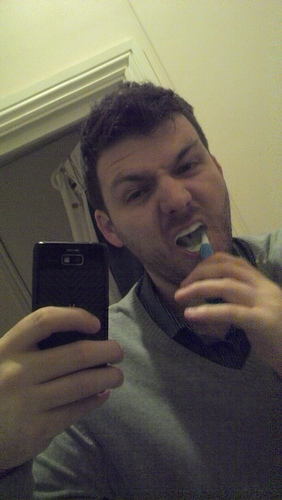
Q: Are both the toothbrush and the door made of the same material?
A: No, the toothbrush is made of plastic and the door is made of wood.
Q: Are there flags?
A: No, there are no flags.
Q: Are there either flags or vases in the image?
A: No, there are no flags or vases.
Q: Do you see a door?
A: Yes, there is a door.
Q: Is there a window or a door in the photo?
A: Yes, there is a door.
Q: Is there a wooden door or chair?
A: Yes, there is a wood door.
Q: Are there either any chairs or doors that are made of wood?
A: Yes, the door is made of wood.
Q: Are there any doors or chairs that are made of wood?
A: Yes, the door is made of wood.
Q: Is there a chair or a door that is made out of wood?
A: Yes, the door is made of wood.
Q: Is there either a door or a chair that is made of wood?
A: Yes, the door is made of wood.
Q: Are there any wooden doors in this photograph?
A: Yes, there is a wood door.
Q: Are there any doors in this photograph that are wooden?
A: Yes, there is a door that is wooden.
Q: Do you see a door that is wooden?
A: Yes, there is a door that is wooden.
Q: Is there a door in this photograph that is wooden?
A: Yes, there is a door that is wooden.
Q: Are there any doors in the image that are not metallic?
A: Yes, there is a wooden door.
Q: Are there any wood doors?
A: Yes, there is a door that is made of wood.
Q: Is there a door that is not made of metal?
A: Yes, there is a door that is made of wood.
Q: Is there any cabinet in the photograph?
A: No, there are no cabinets.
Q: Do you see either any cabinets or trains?
A: No, there are no cabinets or trains.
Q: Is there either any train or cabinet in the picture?
A: No, there are no cabinets or trains.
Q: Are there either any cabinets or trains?
A: No, there are no cabinets or trains.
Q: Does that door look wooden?
A: Yes, the door is wooden.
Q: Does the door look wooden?
A: Yes, the door is wooden.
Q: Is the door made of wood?
A: Yes, the door is made of wood.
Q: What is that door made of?
A: The door is made of wood.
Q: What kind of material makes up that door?
A: The door is made of wood.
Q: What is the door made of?
A: The door is made of wood.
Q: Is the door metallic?
A: No, the door is wooden.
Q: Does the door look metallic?
A: No, the door is wooden.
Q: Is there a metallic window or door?
A: No, there is a door but it is wooden.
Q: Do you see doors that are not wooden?
A: No, there is a door but it is wooden.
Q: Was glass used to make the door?
A: No, the door is made of wood.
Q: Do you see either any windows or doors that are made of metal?
A: No, there is a door but it is made of wood.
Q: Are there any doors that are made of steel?
A: No, there is a door but it is made of wood.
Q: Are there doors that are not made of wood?
A: No, there is a door but it is made of wood.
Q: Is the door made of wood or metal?
A: The door is made of wood.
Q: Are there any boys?
A: No, there are no boys.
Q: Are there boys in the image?
A: No, there are no boys.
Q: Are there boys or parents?
A: No, there are no boys or parents.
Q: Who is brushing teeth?
A: The man is brushing teeth.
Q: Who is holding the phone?
A: The man is holding the telephone.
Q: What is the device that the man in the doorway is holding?
A: The device is a phone.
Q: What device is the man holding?
A: The man is holding the telephone.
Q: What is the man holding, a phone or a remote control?
A: The man is holding a phone.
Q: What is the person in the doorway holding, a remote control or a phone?
A: The man is holding a phone.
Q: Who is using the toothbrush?
A: The man is using the toothbrush.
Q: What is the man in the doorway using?
A: The man is using a toothbrush.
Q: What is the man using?
A: The man is using a toothbrush.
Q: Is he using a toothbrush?
A: Yes, the man is using a toothbrush.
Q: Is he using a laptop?
A: No, the man is using a toothbrush.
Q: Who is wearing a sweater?
A: The man is wearing a sweater.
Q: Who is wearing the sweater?
A: The man is wearing a sweater.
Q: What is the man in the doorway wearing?
A: The man is wearing a sweater.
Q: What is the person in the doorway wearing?
A: The man is wearing a sweater.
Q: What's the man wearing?
A: The man is wearing a sweater.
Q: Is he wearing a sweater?
A: Yes, the man is wearing a sweater.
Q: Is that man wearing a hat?
A: No, the man is wearing a sweater.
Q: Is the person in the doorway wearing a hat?
A: No, the man is wearing a sweater.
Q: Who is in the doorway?
A: The man is in the doorway.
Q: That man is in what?
A: The man is in the doorway.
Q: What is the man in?
A: The man is in the doorway.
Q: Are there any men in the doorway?
A: Yes, there is a man in the doorway.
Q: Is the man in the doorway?
A: Yes, the man is in the doorway.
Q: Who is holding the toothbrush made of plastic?
A: The man is holding the toothbrush.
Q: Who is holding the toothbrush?
A: The man is holding the toothbrush.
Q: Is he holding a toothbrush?
A: Yes, the man is holding a toothbrush.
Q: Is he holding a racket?
A: No, the man is holding a toothbrush.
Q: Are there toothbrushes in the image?
A: Yes, there is a toothbrush.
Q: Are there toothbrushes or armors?
A: Yes, there is a toothbrush.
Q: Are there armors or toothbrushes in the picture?
A: Yes, there is a toothbrush.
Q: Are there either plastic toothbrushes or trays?
A: Yes, there is a plastic toothbrush.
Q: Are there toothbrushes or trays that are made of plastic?
A: Yes, the toothbrush is made of plastic.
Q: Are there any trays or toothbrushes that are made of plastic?
A: Yes, the toothbrush is made of plastic.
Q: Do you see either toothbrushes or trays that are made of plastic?
A: Yes, the toothbrush is made of plastic.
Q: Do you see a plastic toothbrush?
A: Yes, there is a toothbrush that is made of plastic.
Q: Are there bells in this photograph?
A: No, there are no bells.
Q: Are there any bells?
A: No, there are no bells.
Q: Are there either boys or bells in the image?
A: No, there are no bells or boys.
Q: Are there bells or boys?
A: No, there are no bells or boys.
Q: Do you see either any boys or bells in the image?
A: No, there are no bells or boys.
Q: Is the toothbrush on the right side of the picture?
A: Yes, the toothbrush is on the right of the image.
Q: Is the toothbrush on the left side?
A: No, the toothbrush is on the right of the image.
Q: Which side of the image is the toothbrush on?
A: The toothbrush is on the right of the image.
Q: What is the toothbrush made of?
A: The toothbrush is made of plastic.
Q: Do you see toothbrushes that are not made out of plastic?
A: No, there is a toothbrush but it is made of plastic.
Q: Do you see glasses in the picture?
A: No, there are no glasses.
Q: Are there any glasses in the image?
A: No, there are no glasses.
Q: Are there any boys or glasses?
A: No, there are no glasses or boys.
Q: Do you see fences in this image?
A: No, there are no fences.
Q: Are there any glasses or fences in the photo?
A: No, there are no fences or glasses.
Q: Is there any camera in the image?
A: Yes, there is a camera.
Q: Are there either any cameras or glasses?
A: Yes, there is a camera.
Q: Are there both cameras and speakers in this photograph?
A: No, there is a camera but no speakers.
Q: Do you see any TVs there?
A: No, there are no tvs.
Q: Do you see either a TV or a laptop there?
A: No, there are no televisions or laptops.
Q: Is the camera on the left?
A: Yes, the camera is on the left of the image.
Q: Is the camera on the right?
A: No, the camera is on the left of the image.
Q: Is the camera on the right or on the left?
A: The camera is on the left of the image.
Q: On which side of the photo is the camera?
A: The camera is on the left of the image.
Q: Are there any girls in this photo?
A: No, there are no girls.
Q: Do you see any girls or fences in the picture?
A: No, there are no girls or fences.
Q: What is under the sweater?
A: The shirt is under the sweater.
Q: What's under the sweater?
A: The shirt is under the sweater.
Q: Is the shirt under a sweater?
A: Yes, the shirt is under a sweater.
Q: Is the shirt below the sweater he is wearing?
A: Yes, the shirt is below the sweater.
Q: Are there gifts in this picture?
A: No, there are no gifts.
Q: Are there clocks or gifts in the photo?
A: No, there are no gifts or clocks.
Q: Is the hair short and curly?
A: Yes, the hair is short and curly.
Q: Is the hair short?
A: Yes, the hair is short.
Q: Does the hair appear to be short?
A: Yes, the hair is short.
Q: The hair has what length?
A: The hair is short.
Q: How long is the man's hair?
A: The hair is short.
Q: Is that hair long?
A: No, the hair is short.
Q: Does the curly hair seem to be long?
A: No, the hair is short.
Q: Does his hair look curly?
A: Yes, the hair is curly.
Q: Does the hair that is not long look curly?
A: Yes, the hair is curly.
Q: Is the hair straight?
A: No, the hair is curly.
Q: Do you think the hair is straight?
A: No, the hair is curly.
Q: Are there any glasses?
A: No, there are no glasses.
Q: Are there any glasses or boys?
A: No, there are no glasses or boys.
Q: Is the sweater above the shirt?
A: Yes, the sweater is above the shirt.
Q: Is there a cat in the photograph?
A: No, there are no cats.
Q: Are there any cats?
A: No, there are no cats.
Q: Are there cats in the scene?
A: No, there are no cats.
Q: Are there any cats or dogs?
A: No, there are no cats or dogs.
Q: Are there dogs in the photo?
A: No, there are no dogs.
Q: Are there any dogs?
A: No, there are no dogs.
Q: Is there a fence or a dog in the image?
A: No, there are no dogs or fences.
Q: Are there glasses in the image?
A: No, there are no glasses.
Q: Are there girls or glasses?
A: No, there are no glasses or girls.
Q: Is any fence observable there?
A: No, there are no fences.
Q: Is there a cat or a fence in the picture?
A: No, there are no fences or cats.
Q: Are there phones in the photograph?
A: Yes, there is a phone.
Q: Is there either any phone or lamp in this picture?
A: Yes, there is a phone.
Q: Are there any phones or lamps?
A: Yes, there is a phone.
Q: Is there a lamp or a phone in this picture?
A: Yes, there is a phone.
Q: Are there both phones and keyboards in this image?
A: No, there is a phone but no keyboards.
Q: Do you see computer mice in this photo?
A: No, there are no computer mice.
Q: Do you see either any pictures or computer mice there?
A: No, there are no computer mice or pictures.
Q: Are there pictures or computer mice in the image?
A: No, there are no computer mice or pictures.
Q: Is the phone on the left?
A: Yes, the phone is on the left of the image.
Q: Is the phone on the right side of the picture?
A: No, the phone is on the left of the image.